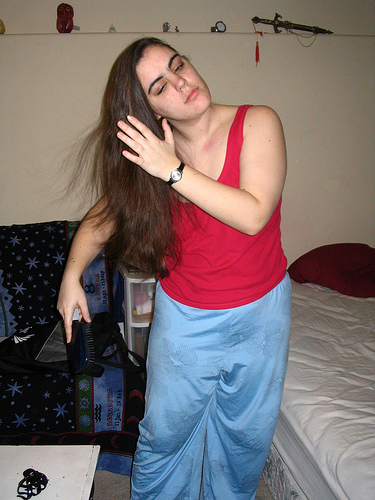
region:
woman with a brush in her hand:
[54, 298, 107, 381]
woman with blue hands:
[147, 299, 291, 496]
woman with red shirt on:
[149, 137, 292, 285]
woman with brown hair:
[90, 56, 174, 296]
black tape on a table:
[14, 464, 54, 498]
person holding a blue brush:
[62, 314, 98, 380]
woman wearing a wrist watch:
[154, 148, 191, 186]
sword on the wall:
[256, 14, 350, 41]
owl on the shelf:
[48, 0, 74, 38]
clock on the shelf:
[211, 18, 230, 33]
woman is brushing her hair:
[18, 26, 304, 498]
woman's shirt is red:
[142, 96, 297, 318]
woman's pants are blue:
[131, 270, 284, 497]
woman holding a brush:
[63, 310, 109, 385]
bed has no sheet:
[243, 268, 372, 495]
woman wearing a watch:
[154, 156, 200, 202]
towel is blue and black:
[2, 208, 131, 437]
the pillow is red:
[280, 222, 373, 303]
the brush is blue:
[53, 306, 108, 374]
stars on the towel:
[8, 221, 123, 441]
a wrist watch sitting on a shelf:
[207, 18, 228, 33]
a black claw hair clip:
[14, 465, 49, 498]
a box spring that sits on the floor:
[262, 455, 287, 496]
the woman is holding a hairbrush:
[63, 297, 99, 368]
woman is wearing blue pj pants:
[135, 293, 295, 497]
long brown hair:
[92, 157, 173, 286]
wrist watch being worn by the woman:
[163, 161, 188, 184]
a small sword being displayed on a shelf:
[246, 7, 338, 68]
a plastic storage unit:
[124, 273, 154, 361]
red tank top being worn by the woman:
[159, 113, 273, 302]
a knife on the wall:
[250, 13, 333, 46]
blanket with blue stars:
[4, 221, 81, 435]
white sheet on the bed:
[278, 281, 371, 495]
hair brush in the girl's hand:
[60, 275, 94, 375]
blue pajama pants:
[129, 283, 289, 498]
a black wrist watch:
[169, 161, 185, 185]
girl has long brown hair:
[82, 37, 183, 277]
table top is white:
[1, 443, 99, 497]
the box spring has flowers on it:
[261, 453, 300, 498]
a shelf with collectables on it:
[0, 19, 362, 38]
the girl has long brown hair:
[89, 35, 218, 281]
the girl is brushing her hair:
[40, 35, 206, 373]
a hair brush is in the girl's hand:
[52, 278, 103, 380]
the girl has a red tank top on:
[146, 107, 287, 308]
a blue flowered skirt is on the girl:
[129, 276, 292, 495]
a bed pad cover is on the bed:
[265, 269, 374, 497]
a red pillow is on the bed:
[290, 231, 373, 301]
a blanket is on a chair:
[1, 217, 132, 444]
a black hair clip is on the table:
[13, 465, 51, 496]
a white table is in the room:
[1, 440, 103, 498]